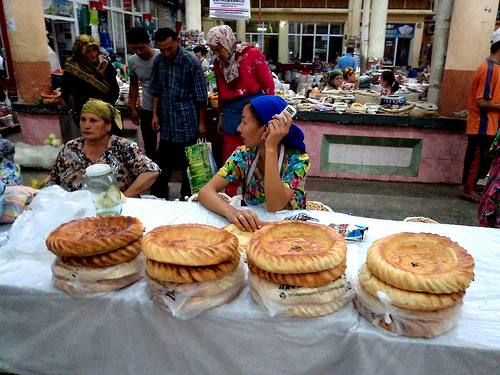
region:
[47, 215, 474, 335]
bread products on table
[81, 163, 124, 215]
glass jar on table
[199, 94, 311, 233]
woman with blue scarf on head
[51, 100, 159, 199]
woman with green scarf on head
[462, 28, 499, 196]
man wearing an orange shirt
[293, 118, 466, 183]
green, red, and white tiles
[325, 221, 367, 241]
blue and white foil packaging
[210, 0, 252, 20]
white sign hanging in the background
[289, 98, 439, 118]
food spread on table in the background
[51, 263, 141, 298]
wrapper around bread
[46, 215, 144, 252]
ethnic bread on the white table cloth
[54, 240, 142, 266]
ethnic bread on the white table cloth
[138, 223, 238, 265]
ethnic bread on the white table cloth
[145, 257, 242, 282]
ethnic bread on the white table cloth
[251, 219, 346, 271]
ethnic bread on the white table cloth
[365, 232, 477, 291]
ethnic bread on the white table cloth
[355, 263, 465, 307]
ethnic bread on the white table cloth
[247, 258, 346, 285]
ethnic bread on the white table cloth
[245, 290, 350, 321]
ethnic bread on the white table cloth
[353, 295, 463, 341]
ethnic bread on the white table cloth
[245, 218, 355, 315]
Stack of handmade bakery item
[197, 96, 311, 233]
Woman holding cell phone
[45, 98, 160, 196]
Woman sitting and looking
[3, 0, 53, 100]
Large brown and tan column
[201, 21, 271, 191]
Woman wearing head scarf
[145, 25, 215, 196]
Man carrying green and white plastic shopping bag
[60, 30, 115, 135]
Woman standing and watching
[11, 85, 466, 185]
Several cooked items on pink and black long table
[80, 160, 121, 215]
Large clear jar with white lid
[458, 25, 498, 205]
Man wearing orange t-shirt with black stripe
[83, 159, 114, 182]
a lid on a jar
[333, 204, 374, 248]
a bag on the table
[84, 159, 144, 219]
a jar on the table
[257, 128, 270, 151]
ear ings in an ear